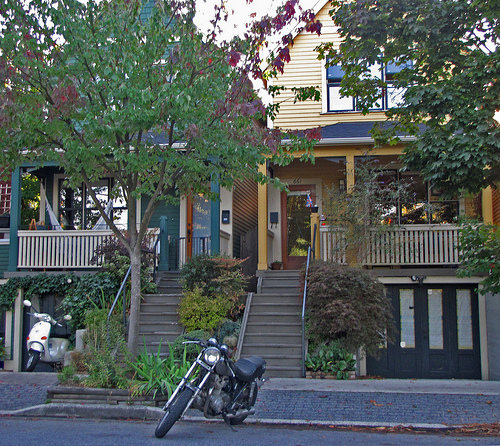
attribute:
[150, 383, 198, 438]
tire — black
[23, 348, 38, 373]
tire — black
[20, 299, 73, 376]
moped — white, here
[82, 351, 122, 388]
weeds — tall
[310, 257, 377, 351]
bush — here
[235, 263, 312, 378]
staircase — here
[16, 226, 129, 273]
railing — white, here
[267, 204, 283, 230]
mailbox — black, here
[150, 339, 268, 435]
motorcycle — parked, black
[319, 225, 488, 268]
rail — wooden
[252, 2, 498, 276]
house — yellow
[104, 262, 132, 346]
rail — iron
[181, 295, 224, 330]
bush — small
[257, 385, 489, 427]
sidewalk — brick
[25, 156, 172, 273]
porch — covered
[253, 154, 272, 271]
post — yellow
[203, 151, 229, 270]
post — green